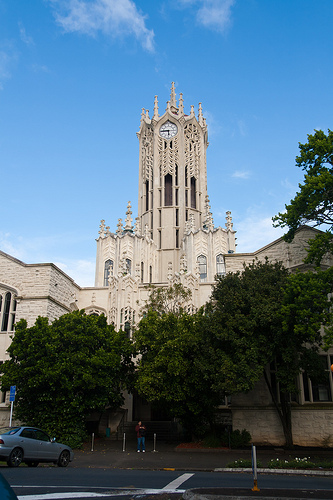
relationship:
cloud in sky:
[49, 0, 166, 61] [0, 0, 332, 288]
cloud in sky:
[171, 0, 238, 37] [0, 0, 332, 288]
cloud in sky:
[49, 0, 166, 61] [33, 105, 116, 149]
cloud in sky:
[157, 0, 238, 39] [0, 0, 332, 288]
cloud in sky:
[225, 164, 254, 184] [0, 0, 332, 288]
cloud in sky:
[227, 197, 329, 255] [0, 0, 332, 288]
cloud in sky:
[2, 221, 98, 286] [0, 0, 332, 288]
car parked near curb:
[0, 423, 72, 467] [74, 453, 332, 478]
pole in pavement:
[150, 433, 158, 452] [1, 440, 330, 466]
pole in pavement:
[121, 432, 126, 451] [1, 440, 330, 466]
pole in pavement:
[89, 432, 94, 450] [1, 440, 330, 466]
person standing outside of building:
[133, 419, 147, 455] [0, 80, 332, 445]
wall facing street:
[216, 392, 332, 453] [1, 466, 323, 498]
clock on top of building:
[158, 119, 178, 139] [0, 80, 332, 445]